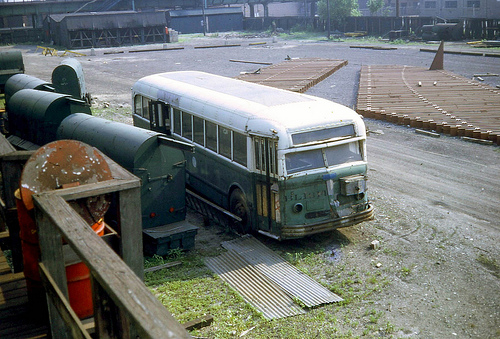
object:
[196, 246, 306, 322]
fence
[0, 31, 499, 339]
ground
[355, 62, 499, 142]
track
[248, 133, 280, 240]
door